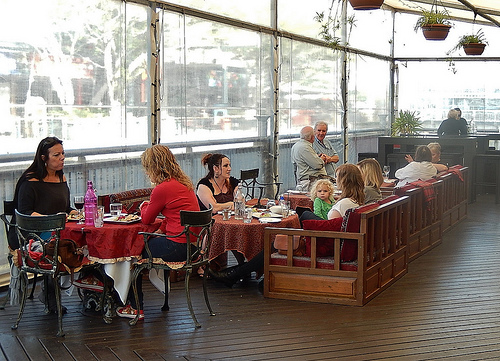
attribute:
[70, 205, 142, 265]
tablecover — red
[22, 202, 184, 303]
tablecloth — red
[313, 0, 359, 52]
plant — green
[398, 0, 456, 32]
plant — green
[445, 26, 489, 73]
plant — green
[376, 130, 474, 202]
dark counter — tall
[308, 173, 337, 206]
girl — little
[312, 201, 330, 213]
shirt — green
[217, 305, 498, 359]
wooden floor — brown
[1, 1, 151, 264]
window — large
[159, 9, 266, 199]
window — large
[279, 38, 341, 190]
window — large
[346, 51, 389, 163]
window — large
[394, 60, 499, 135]
window — large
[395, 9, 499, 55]
window — large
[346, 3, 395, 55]
window — large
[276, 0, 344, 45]
window — large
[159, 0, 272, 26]
window — large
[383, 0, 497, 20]
window — large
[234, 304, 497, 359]
wood — dark, brown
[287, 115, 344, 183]
men — gray haired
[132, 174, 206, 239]
shirt — red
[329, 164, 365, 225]
head — brown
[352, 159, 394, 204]
head — blonde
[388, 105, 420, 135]
plant — small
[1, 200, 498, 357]
floor — wood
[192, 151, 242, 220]
diner — hungry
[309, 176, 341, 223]
girl — young, blonde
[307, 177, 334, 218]
girl — little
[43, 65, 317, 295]
setting — restaurant-style